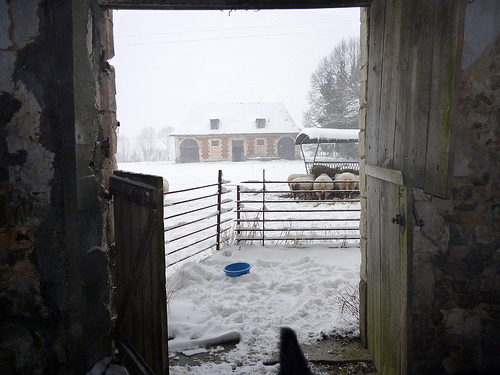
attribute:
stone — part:
[280, 325, 311, 373]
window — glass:
[201, 137, 231, 151]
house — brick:
[171, 100, 304, 161]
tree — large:
[311, 56, 364, 135]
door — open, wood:
[349, 4, 469, 373]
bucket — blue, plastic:
[223, 261, 254, 276]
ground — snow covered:
[126, 157, 309, 195]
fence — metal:
[234, 176, 367, 247]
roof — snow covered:
[167, 108, 299, 137]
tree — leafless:
[321, 54, 365, 131]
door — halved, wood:
[109, 163, 177, 370]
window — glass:
[252, 137, 267, 146]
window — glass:
[229, 138, 247, 148]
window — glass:
[207, 115, 225, 132]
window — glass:
[255, 140, 287, 163]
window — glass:
[167, 139, 188, 148]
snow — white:
[229, 235, 343, 326]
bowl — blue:
[214, 243, 257, 278]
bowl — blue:
[216, 250, 275, 288]